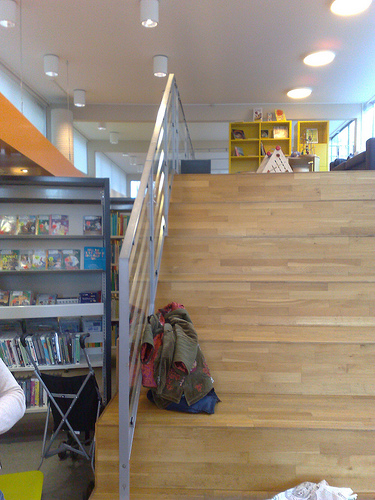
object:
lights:
[287, 84, 316, 105]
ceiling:
[0, 0, 375, 166]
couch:
[329, 136, 375, 171]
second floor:
[176, 166, 372, 174]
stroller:
[19, 332, 94, 419]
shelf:
[0, 229, 107, 245]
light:
[301, 44, 340, 70]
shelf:
[229, 133, 261, 142]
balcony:
[117, 71, 195, 498]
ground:
[0, 432, 84, 499]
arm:
[0, 355, 33, 438]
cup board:
[295, 116, 332, 176]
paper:
[270, 477, 359, 499]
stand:
[110, 73, 193, 498]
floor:
[0, 428, 90, 499]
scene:
[0, 1, 375, 499]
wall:
[0, 90, 87, 177]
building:
[0, 0, 375, 498]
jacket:
[137, 296, 218, 413]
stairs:
[87, 164, 375, 498]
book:
[45, 249, 66, 270]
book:
[61, 247, 79, 269]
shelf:
[0, 260, 107, 275]